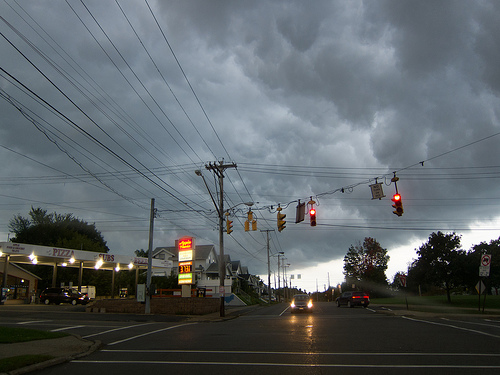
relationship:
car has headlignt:
[290, 293, 314, 316] [305, 299, 313, 314]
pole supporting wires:
[214, 234, 227, 287] [176, 65, 215, 166]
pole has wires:
[214, 234, 227, 287] [176, 65, 215, 166]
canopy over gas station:
[0, 242, 174, 272] [2, 264, 167, 310]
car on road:
[290, 293, 314, 316] [1, 292, 500, 372]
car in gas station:
[42, 286, 92, 305] [2, 264, 167, 310]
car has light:
[290, 293, 314, 316] [289, 298, 296, 310]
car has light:
[334, 289, 369, 312] [354, 296, 360, 299]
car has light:
[334, 289, 369, 312] [362, 294, 368, 301]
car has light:
[42, 286, 92, 305] [77, 294, 86, 304]